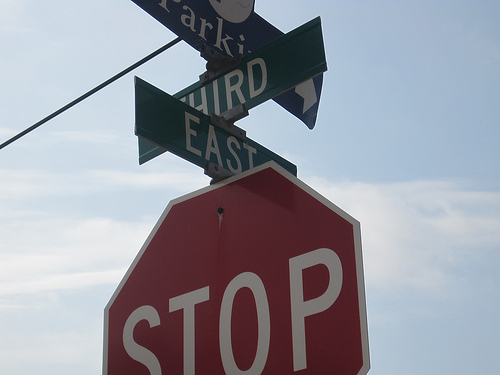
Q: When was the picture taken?
A: Daytime.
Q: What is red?
A: Sign.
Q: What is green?
A: Small signs.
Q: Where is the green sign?
A: Above the stop sign.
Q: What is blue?
A: Sky.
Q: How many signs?
A: Four.